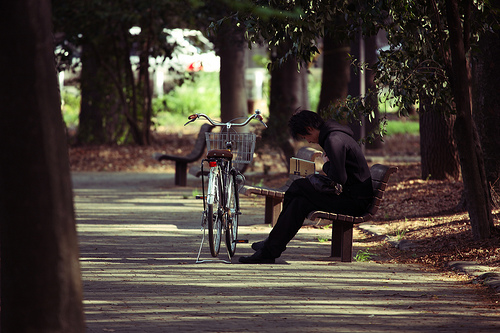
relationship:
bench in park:
[237, 148, 406, 266] [0, 3, 493, 331]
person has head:
[237, 95, 372, 272] [287, 108, 319, 140]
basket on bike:
[203, 129, 258, 164] [178, 103, 265, 256]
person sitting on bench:
[237, 95, 372, 272] [237, 127, 406, 266]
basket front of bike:
[206, 132, 261, 169] [183, 108, 261, 256]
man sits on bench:
[271, 81, 377, 285] [285, 152, 401, 268]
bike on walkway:
[178, 103, 265, 256] [69, 159, 254, 331]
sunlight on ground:
[84, 216, 172, 257] [79, 202, 186, 307]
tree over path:
[367, 2, 497, 267] [54, 127, 302, 330]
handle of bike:
[191, 110, 269, 127] [183, 100, 270, 260]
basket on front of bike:
[203, 129, 258, 164] [124, 74, 310, 298]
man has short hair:
[271, 81, 377, 285] [283, 99, 323, 125]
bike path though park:
[56, 180, 492, 329] [0, 3, 493, 331]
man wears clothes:
[271, 81, 377, 285] [246, 135, 380, 261]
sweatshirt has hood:
[317, 120, 377, 202] [319, 115, 356, 135]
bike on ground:
[178, 103, 265, 256] [176, 103, 271, 291]